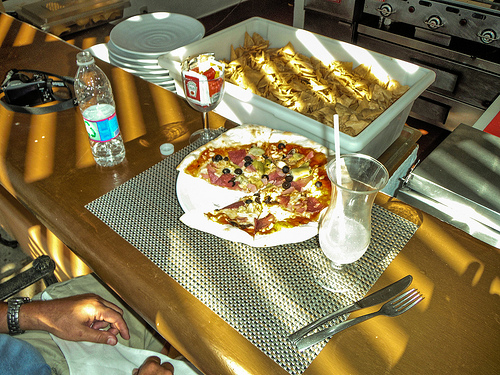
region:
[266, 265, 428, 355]
The fork and knife are made of metal.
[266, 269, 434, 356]
A fork and knife.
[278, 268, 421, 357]
The fork and knife are gray.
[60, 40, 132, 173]
A plastic bottle of water.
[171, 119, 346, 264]
A pizza.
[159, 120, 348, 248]
The pizza is round.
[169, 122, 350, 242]
A slice is missing from the pizza.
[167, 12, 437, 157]
A large box of chips.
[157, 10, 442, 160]
The box is white and rectangular.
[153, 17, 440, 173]
The box is made of plastic.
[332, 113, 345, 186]
a white straw in a glass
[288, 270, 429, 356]
a fork and knife resting on a placemat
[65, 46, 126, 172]
a water bottle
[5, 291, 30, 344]
a watch on a man's wrist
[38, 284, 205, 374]
a napkin in a lap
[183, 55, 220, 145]
sauce packets in a wine glass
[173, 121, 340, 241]
a pizza with a slice missing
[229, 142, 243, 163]
pink ham on a pizza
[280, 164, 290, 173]
a black olive on a pizza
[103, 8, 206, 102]
a stack of plates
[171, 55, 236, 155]
wine glass full of ketchup packets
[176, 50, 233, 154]
glass full of condiments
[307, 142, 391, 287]
tall tiki style cup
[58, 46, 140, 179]
plastic water bottle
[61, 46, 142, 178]
water bottle with blue label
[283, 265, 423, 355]
silver eating utensils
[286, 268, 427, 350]
fork and butter knife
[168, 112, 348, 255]
pizza with lots of toppings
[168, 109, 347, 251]
pizza with olives and peppers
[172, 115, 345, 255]
pizza with sauce and cheese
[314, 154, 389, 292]
A shapely glass with liquid and straw inside.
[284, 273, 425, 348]
Eating utensils folk and knife.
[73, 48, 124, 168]
Nearly empty water bottle.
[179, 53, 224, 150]
Glass full of Ketchup packets.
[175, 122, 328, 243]
Pizza with many toppings.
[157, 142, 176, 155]
Cap to plastic water bottle.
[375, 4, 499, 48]
Silver and black dials to the stove.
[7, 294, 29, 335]
Man's silver wrist watch.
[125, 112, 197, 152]
Shadow of water bottle on table.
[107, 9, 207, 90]
Stack of white saucers.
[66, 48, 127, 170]
a clear plastic water bottle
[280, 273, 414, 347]
a silver knife utensil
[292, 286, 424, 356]
a silver fork utensil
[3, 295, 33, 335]
a man's silver watch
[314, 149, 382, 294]
a clear fluted glass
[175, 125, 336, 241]
a pizza pie missing a slice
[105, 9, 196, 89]
a stack of white plates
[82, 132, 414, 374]
a white and black placemat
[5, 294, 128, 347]
a man's left hand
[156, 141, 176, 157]
a plastic bottle lid